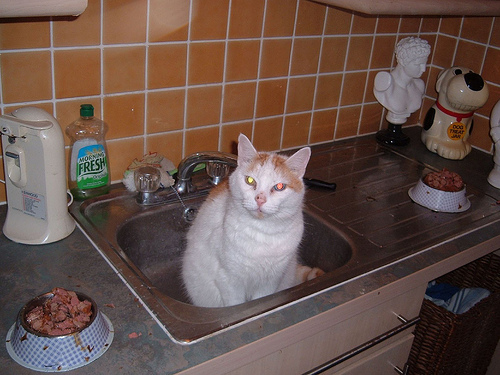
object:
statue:
[361, 29, 442, 136]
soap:
[55, 99, 123, 209]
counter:
[0, 108, 499, 373]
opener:
[0, 100, 85, 252]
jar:
[407, 57, 497, 168]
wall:
[0, 0, 500, 219]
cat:
[160, 124, 343, 314]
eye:
[238, 172, 260, 194]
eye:
[267, 175, 289, 198]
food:
[15, 280, 100, 339]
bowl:
[0, 279, 123, 374]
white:
[33, 143, 58, 188]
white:
[389, 87, 415, 103]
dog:
[411, 58, 495, 165]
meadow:
[56, 96, 116, 210]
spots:
[205, 146, 267, 209]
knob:
[120, 159, 175, 208]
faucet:
[127, 134, 342, 207]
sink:
[96, 180, 379, 322]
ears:
[229, 125, 269, 171]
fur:
[191, 218, 308, 304]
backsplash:
[0, 0, 498, 207]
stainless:
[53, 122, 500, 357]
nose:
[250, 191, 272, 212]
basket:
[393, 244, 499, 373]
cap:
[74, 101, 99, 123]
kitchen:
[0, 0, 500, 375]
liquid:
[63, 178, 116, 205]